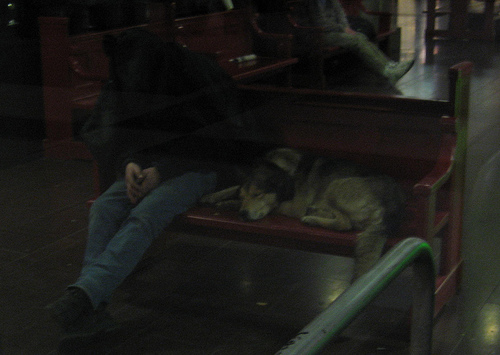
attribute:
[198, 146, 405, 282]
dog — brown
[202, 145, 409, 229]
dog — asleep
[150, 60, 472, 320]
seat — silver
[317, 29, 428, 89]
pants — khaki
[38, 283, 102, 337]
shoe — black, men's, tennis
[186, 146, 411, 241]
dog — asleep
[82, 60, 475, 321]
seat — silver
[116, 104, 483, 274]
seat — silver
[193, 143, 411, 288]
dog — asleep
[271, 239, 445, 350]
railing — silver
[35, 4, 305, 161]
bench — longer, red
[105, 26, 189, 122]
head — covered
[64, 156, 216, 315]
jeans — blue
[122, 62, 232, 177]
jacket — black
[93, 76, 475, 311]
bench — red, wooden